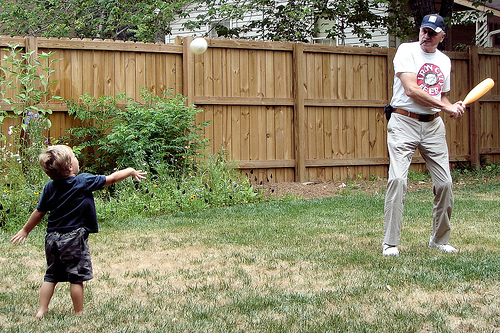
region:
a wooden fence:
[3, 35, 499, 183]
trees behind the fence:
[24, 3, 415, 25]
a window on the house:
[310, 13, 336, 47]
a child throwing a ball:
[23, 143, 127, 308]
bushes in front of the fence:
[72, 98, 185, 155]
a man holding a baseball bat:
[381, 17, 485, 274]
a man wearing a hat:
[385, 13, 477, 248]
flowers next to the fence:
[176, 173, 271, 203]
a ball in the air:
[184, 37, 214, 57]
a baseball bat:
[458, 78, 498, 100]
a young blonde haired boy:
[11, 143, 146, 318]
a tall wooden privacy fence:
[0, 33, 499, 173]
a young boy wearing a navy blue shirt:
[10, 142, 149, 318]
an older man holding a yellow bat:
[382, 13, 496, 260]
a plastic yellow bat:
[462, 77, 494, 106]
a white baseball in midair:
[189, 38, 210, 55]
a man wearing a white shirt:
[381, 13, 465, 255]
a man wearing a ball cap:
[380, 8, 462, 253]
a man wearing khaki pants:
[381, 8, 463, 255]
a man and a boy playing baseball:
[7, 15, 493, 318]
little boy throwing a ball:
[11, 145, 146, 310]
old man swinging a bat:
[378, 14, 492, 259]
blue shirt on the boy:
[34, 172, 106, 230]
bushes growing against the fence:
[0, 44, 258, 226]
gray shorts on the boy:
[38, 226, 94, 285]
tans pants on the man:
[381, 114, 451, 249]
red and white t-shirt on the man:
[390, 44, 452, 111]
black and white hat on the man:
[416, 13, 445, 35]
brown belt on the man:
[391, 107, 441, 124]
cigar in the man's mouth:
[418, 38, 428, 48]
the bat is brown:
[455, 70, 495, 121]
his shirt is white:
[389, 52, 459, 113]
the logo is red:
[414, 58, 451, 95]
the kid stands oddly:
[5, 125, 161, 319]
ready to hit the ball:
[366, 62, 493, 123]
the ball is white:
[176, 28, 212, 82]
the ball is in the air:
[182, 28, 219, 68]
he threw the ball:
[10, 90, 225, 230]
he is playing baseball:
[344, 10, 482, 245]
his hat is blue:
[413, 14, 456, 33]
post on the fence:
[294, 38, 311, 185]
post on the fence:
[279, 44, 294, 184]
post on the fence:
[265, 47, 274, 194]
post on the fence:
[255, 45, 262, 200]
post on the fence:
[242, 42, 254, 193]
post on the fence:
[306, 48, 320, 200]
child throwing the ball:
[0, 147, 105, 310]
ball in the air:
[181, 38, 205, 62]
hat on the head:
[417, 12, 450, 31]